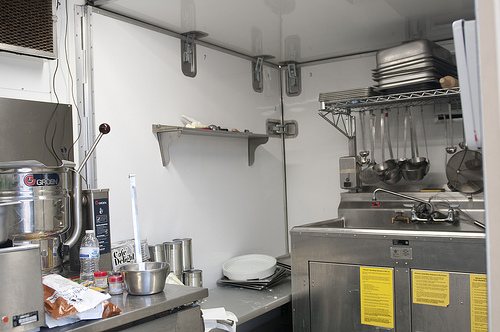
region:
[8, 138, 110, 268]
A mixing bowl on a counter.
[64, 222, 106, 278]
Bottle of water on the counter.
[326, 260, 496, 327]
Yellow signs on the sink.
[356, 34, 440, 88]
Pans on top of a shelf.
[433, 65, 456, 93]
Rolling pin on top of a shelf.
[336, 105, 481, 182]
Ladles hanging from the shelf.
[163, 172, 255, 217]
The wall is white.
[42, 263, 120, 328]
Bags on the counter.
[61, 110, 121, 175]
Handle of the bowl is silver.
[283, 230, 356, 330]
The sink is silver.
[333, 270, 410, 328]
the paper is yellow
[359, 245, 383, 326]
the paper is yellow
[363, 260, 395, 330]
the paper is yellow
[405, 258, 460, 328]
the paper is yellow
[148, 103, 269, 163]
shelf on wall above counter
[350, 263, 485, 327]
yellow instruction stickers on equipment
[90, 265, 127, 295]
two spice bottles on counter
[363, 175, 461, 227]
water faucet on sink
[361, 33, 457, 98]
stack of warming pans above sink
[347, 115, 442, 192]
ladles hanging from hooks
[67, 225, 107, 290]
disposable bottle of water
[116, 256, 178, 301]
mixing bowl on counter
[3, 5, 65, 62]
exhaust vent on wall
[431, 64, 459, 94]
rolling pin on shelf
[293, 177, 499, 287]
Stainless steel kitchen sink.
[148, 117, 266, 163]
Shelf on wall.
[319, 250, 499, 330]
Three yellow tags on kitchen appliance.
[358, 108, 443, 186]
Hanging kitchen utensils.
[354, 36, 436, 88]
Stack of stainless steel pans.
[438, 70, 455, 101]
Wooden kitchen rolling pin.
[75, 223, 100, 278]
Botttle of water.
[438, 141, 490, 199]
Kitchen strainer above sink.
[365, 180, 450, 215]
Stainless steel kitchen faucet.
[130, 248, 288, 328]
Stainless steel kitchen counters.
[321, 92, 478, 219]
pots and pans hanging from a rack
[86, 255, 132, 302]
spices on the kitchen counter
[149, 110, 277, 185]
a metal shelf hanging on the wall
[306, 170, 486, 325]
a large stainless steel kitchen sink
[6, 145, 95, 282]
a large stainless steel mixer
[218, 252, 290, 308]
a white cake pan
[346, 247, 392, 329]
a yellow instruction sign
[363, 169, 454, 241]
a stainless steel faucet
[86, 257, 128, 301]
bottles of spices on the counter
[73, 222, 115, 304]
a plastic water bottle on the table